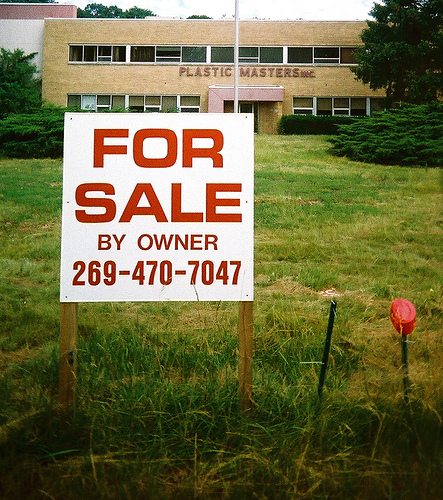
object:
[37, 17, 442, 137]
brick building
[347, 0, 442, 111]
tree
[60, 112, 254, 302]
sign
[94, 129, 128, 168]
f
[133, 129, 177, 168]
o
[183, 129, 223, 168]
r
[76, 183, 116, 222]
s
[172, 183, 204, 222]
l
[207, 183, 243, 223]
e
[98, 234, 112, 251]
b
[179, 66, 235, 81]
words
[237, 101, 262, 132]
entrance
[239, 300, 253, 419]
wood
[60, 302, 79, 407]
wood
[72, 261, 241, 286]
contact information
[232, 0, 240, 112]
pole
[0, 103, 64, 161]
shrubs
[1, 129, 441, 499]
lawn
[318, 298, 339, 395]
pole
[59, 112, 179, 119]
edges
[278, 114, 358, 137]
shrub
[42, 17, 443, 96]
upper floor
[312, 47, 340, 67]
windows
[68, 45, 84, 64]
window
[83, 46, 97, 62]
window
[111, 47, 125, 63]
window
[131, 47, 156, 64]
window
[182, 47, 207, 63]
window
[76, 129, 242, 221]
for sale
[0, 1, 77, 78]
building